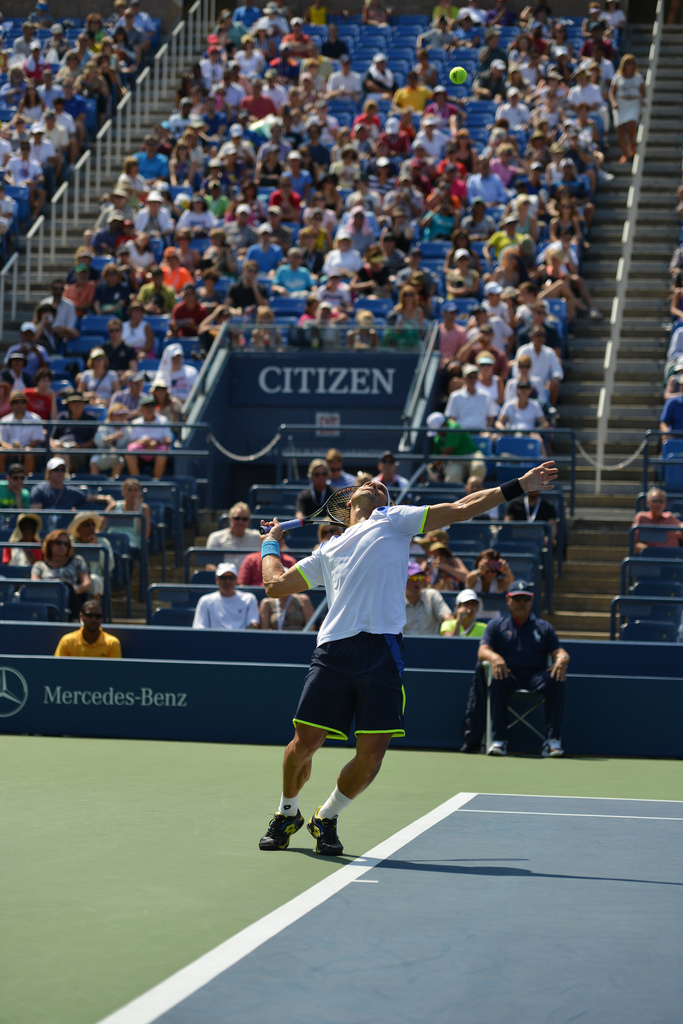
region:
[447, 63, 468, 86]
the green tennis ball in the air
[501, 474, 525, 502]
the black wristband on the player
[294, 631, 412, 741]
the blue shorts on the palyer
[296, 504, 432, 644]
the shirt on the player is white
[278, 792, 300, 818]
the sock on the player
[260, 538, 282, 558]
the blue wristband on the player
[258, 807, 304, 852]
the tennis shoe is black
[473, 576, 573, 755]
the man sitting in the chair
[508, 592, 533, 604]
the black glasses on the man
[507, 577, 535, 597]
the blue hat on the mans head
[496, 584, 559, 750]
A man sitting on a chair.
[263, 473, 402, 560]
A man holding a tennis racket.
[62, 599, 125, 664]
A man in a yellow shirt.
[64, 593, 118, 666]
A man in a yellow shirt wearing shades.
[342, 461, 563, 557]
A young man raising up his hand.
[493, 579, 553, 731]
An adult man sitting is wearing a cap.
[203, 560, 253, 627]
A man in a white shirt and cap.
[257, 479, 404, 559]
The man is wearing a blue wristband.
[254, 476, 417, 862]
The man's feet are tip toed.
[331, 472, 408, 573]
The young man is looking up.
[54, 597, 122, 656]
person is at a stadium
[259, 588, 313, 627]
person is at a stadium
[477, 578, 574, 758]
person is at a stadium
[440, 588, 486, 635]
person is at a stadium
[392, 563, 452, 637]
person is at a stadium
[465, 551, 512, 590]
person is at a stadium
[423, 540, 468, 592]
person is at a stadium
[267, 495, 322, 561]
person is at a stadium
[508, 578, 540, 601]
a blue baseball cap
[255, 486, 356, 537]
a blue and black tennis racket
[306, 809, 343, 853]
a man's black tennis shoe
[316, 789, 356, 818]
a tall white sock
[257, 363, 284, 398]
a white capital letter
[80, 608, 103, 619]
dark black sunglasses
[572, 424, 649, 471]
small gray chain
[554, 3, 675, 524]
a row of steps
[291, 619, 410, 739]
a man's blue and green shorts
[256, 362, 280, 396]
A large C in CITIZEN.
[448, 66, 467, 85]
A green round tennis ball.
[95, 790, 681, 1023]
A white lined blue section of court.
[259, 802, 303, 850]
A mans right black shoe.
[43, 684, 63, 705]
Large grey M in Mercedes-Benz.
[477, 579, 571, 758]
Man sitting in a chair on the court in a blue and red hat.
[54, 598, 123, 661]
A man in a yellow shirt wearing black glasses behind the Mercedes name.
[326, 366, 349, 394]
A grey Z in CITIZEN.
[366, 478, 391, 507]
White headband on a tennis player.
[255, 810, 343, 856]
a blue and yellow pair of sneakers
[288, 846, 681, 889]
shadow of the tennis player on the court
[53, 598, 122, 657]
a person wearing a yellow shirt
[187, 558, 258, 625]
a person wearing a white shirt and baseball cap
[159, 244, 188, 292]
a person wearing an orange shirt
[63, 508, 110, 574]
a person wearing a white shirt and a hat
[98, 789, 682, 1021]
white lines surrounding the blue area of the tennis court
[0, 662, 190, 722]
an advertisement on the blue wall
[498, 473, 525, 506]
a black thick wrist brand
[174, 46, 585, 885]
man hitting a ball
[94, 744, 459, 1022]
white line on the court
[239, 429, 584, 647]
man is looking up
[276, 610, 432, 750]
blue pair of pants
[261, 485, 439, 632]
man wearing a white shirt